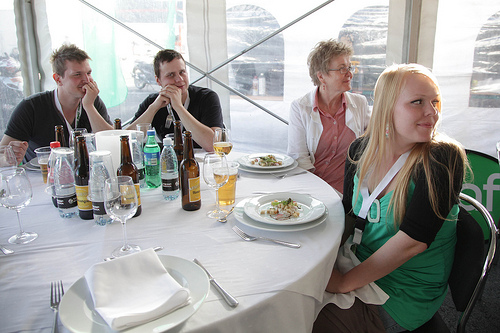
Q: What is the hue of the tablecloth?
A: White.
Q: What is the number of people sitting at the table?
A: Four.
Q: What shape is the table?
A: Round.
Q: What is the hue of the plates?
A: White.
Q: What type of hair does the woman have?
A: Long blonde hair.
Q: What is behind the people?
A: Windows.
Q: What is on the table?
A: Plates, Bottles, and silverware.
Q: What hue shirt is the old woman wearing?
A: Pink.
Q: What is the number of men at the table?
A: Two.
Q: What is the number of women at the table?
A: Two.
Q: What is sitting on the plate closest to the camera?
A: A napkin.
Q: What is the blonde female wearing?
A: A green and black shirt.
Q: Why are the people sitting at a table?
A: For a meal.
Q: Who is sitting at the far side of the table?
A: Two men.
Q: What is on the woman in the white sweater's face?
A: Glasses.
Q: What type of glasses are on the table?
A: Wine.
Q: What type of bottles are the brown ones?
A: Beer.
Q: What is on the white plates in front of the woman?
A: Food.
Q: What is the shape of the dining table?
A: Round.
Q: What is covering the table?
A: White tablecloth.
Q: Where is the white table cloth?
A: On the table.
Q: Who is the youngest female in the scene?
A: Blonde on the end.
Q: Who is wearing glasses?
A: Woman in pink and white.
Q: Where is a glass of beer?
A: In front of blond woman.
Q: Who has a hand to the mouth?
A: Both men.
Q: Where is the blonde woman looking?
A: Over her left shoulder.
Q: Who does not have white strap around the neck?
A: Woman in glasses.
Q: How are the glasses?
A: Empty.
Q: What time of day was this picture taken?
A: Afternoon.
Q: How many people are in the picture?
A: Four.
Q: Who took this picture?
A: Photographer.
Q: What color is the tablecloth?
A: White.